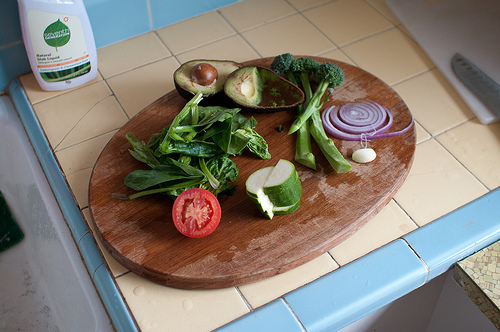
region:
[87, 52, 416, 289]
an oval shaped cutting board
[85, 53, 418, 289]
a wooden cutting board on the counter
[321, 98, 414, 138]
a thin slice of a purple onion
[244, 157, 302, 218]
a sliced portion of a cucumber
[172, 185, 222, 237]
a ripe tomato sliced in half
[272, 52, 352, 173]
three stalks of fresh broccoli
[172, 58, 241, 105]
half of an avocado with the pit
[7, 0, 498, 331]
tan and blue ceramic tiles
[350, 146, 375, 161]
one peeled clove of garlic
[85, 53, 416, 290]
a tray full of vegetables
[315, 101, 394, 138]
onion on the board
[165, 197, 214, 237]
tomato on the board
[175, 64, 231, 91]
avocado on the board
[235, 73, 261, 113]
avocado on the board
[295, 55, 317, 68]
broccoli on the board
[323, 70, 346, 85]
broccoli on the board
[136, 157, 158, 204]
spinach on the board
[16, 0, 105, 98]
a white bottle of soap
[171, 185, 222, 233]
a sliced red tomato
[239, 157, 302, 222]
a sliced cucumber on a cutting board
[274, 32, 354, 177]
a stalk of broccoli on a cutting board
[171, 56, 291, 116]
a sliced avacado on a cutting board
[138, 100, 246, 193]
mixed greens on a cutting board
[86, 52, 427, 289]
a wooden cutting board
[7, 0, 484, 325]
a blue and white tiled counter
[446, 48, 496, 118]
a butchers knife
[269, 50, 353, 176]
three stalks of broccoli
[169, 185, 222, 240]
tomato cut in half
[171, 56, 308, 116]
partially used cut avocado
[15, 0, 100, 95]
plastic container of dish liquid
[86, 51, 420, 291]
partially wet cutting board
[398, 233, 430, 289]
grout missing between tiles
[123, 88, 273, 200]
chopped fresh spinach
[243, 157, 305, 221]
zucchini sliced and cut in half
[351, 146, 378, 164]
a clove of garlic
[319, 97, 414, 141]
one slice of red onion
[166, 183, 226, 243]
half of red tomato on wooden cutting board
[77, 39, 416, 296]
wooden cutting board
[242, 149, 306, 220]
sliced cucumbers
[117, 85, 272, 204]
green leaves on wooden cutting board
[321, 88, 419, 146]
sliced onions on wooden cutting board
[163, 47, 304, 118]
sliced avocado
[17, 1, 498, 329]
yellow tiles on counter top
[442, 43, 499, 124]
knife blade on counter top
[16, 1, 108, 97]
white plastic bottle on counter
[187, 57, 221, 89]
avocado seed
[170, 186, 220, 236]
slice of red tomato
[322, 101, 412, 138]
slice of red onion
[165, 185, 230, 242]
red tomato on cutting board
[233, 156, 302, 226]
sliced zucchini on cutting board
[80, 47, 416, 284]
wooden brown cutting board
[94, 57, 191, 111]
yellow tile on counter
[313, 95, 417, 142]
sliced onions on cutting board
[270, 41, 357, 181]
sliced broccoli on cutting board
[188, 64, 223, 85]
pit of the avocado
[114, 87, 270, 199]
green leaves on the cutting board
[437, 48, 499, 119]
metal knife on the counter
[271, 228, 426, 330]
blue tile on the counter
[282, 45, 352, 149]
brocolli on th etray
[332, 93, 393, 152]
onion on the tray